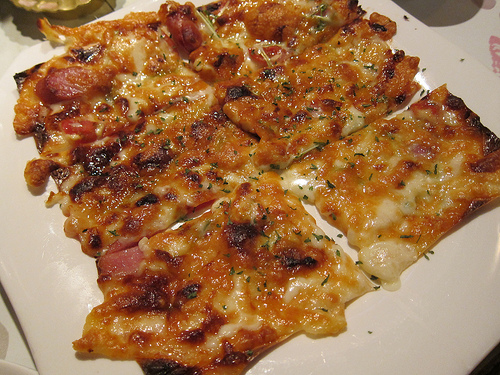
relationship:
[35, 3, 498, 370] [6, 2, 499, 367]
sausage on pizza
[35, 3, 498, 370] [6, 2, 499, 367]
sausage top of pizza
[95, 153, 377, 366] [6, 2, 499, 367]
slice on plate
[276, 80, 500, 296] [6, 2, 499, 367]
slice on plate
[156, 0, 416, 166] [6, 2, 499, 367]
piece on plate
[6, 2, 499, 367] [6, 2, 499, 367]
food on plate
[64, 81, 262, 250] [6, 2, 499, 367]
piece on plate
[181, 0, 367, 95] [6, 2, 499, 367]
piece on plate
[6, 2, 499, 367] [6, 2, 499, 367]
plate with food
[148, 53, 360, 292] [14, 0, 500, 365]
parsley on top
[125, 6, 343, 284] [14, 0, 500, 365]
garlic on top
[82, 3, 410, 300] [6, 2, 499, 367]
oil on food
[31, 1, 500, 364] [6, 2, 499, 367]
cheese on food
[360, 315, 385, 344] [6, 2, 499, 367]
speck on plate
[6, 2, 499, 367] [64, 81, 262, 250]
pizza into piece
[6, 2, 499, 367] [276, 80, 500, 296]
pizza into slice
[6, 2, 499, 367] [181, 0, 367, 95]
pizza into piece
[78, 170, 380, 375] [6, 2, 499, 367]
slice on pizza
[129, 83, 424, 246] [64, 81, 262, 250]
space between piece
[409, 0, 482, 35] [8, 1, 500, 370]
shadow in photo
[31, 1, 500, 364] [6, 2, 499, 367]
cheese hanging off pizza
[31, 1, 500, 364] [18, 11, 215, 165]
pie has corner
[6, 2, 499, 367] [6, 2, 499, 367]
pizza on dish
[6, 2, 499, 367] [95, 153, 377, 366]
pizza in slice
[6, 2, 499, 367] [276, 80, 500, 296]
pizza in slice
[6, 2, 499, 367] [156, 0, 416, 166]
pizza in piece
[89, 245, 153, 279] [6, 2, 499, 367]
ham on pizza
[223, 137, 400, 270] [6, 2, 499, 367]
herbs on pizza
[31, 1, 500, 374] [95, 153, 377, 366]
cheese in slice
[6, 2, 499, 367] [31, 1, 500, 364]
pizza has cheese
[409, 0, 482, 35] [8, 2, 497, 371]
shadow on table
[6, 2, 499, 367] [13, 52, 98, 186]
pizza has border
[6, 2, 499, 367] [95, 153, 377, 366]
pizza cut into slice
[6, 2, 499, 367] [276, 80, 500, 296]
pizza cut into slice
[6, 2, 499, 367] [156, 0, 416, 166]
pizza cut into piece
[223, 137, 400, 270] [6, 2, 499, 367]
herbs of pizza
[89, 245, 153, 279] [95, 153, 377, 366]
ham on slice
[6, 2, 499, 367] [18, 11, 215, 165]
pizza has corner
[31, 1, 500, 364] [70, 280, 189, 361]
cheese has piece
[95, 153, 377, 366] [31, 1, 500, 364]
slice with cheese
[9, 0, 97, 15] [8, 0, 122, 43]
cotainer has shadow